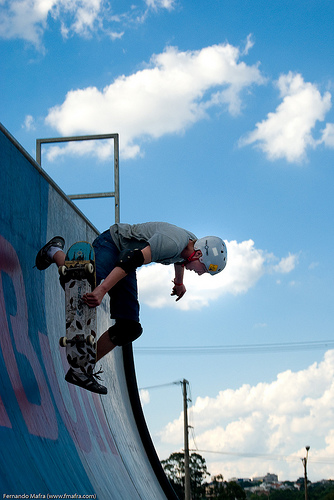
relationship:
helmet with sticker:
[195, 234, 227, 275] [207, 262, 219, 271]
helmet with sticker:
[195, 234, 227, 275] [203, 238, 210, 255]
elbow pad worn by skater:
[114, 247, 145, 274] [34, 220, 228, 395]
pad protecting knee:
[108, 319, 143, 352] [114, 306, 143, 352]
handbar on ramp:
[34, 130, 120, 231] [0, 123, 183, 498]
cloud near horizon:
[164, 347, 330, 493] [161, 442, 323, 488]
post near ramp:
[300, 448, 312, 492] [14, 128, 220, 496]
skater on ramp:
[34, 220, 228, 395] [0, 123, 180, 498]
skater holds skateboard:
[31, 220, 278, 309] [55, 236, 101, 374]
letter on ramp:
[2, 231, 71, 444] [4, 127, 187, 477]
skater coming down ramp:
[34, 220, 228, 395] [0, 123, 183, 498]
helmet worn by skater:
[193, 234, 228, 278] [34, 220, 228, 395]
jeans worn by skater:
[80, 211, 133, 317] [48, 176, 264, 332]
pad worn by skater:
[107, 319, 142, 349] [34, 220, 228, 395]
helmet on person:
[193, 234, 228, 278] [30, 221, 228, 395]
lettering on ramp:
[0, 239, 119, 456] [1, 161, 144, 474]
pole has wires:
[163, 374, 203, 498] [135, 374, 190, 392]